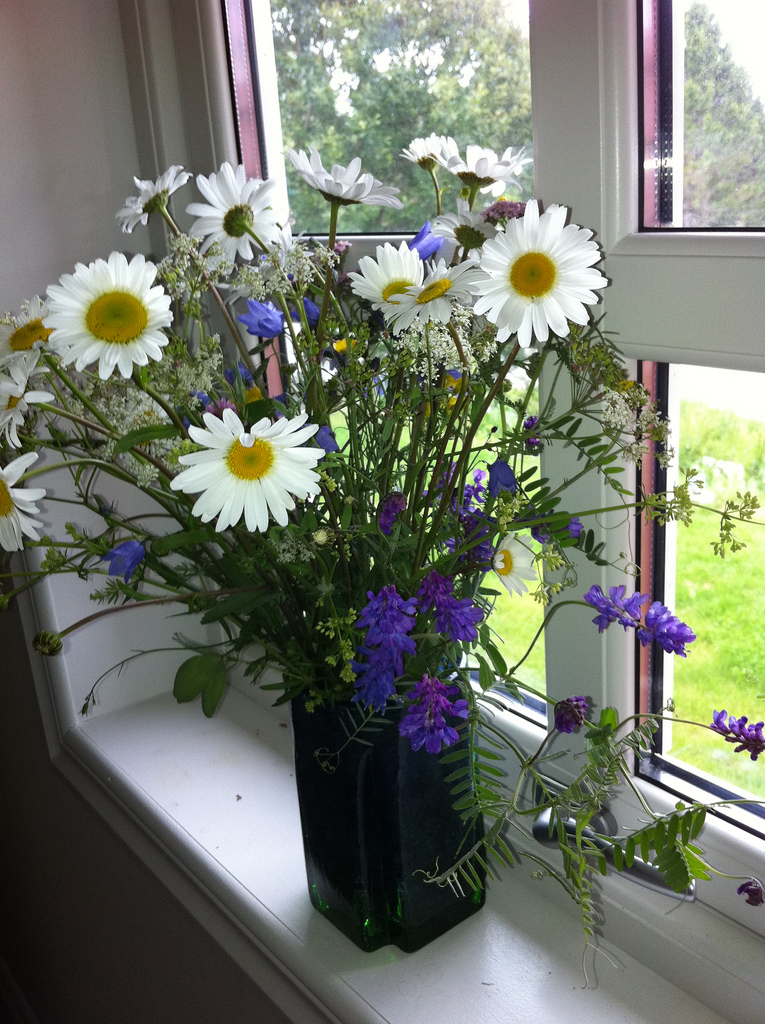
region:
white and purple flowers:
[100, 168, 655, 738]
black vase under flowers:
[240, 647, 515, 994]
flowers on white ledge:
[76, 433, 572, 1003]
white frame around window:
[222, 20, 746, 887]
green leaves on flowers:
[76, 103, 720, 811]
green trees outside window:
[268, 0, 488, 227]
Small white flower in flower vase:
[172, 408, 330, 535]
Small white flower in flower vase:
[463, 191, 611, 353]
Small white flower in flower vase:
[42, 240, 170, 384]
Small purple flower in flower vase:
[391, 663, 481, 758]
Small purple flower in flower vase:
[338, 578, 427, 715]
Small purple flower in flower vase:
[420, 559, 488, 654]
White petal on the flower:
[520, 187, 537, 248]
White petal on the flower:
[201, 412, 235, 446]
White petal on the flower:
[257, 474, 297, 530]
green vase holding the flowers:
[259, 638, 503, 958]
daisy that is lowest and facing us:
[167, 402, 332, 554]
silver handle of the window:
[532, 762, 710, 929]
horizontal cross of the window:
[236, 212, 760, 379]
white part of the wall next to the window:
[0, 13, 175, 253]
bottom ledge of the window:
[88, 682, 714, 1021]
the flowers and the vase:
[1, 128, 763, 948]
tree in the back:
[273, 2, 525, 243]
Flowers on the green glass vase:
[1, 128, 761, 956]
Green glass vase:
[281, 683, 490, 955]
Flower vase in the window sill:
[0, 2, 759, 1021]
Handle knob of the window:
[524, 769, 697, 902]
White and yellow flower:
[168, 404, 327, 535]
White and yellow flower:
[39, 247, 175, 381]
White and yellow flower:
[467, 197, 611, 352]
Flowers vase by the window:
[2, 3, 763, 1019]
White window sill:
[32, 671, 760, 1019]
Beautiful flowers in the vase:
[1, 128, 760, 955]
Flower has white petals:
[39, 248, 174, 381]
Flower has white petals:
[467, 196, 611, 353]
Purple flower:
[95, 539, 147, 580]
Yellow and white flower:
[165, 405, 328, 535]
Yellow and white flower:
[467, 197, 610, 349]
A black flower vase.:
[292, 651, 489, 937]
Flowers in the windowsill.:
[4, 81, 762, 1005]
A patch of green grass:
[316, 358, 761, 806]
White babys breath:
[73, 229, 734, 588]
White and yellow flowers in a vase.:
[5, 114, 607, 644]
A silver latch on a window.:
[532, 773, 682, 897]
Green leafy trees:
[264, 3, 761, 359]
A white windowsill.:
[55, 620, 692, 1021]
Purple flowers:
[322, 402, 761, 810]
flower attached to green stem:
[40, 249, 171, 376]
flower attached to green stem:
[0, 360, 59, 447]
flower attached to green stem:
[0, 447, 55, 558]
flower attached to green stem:
[165, 400, 322, 530]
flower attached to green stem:
[120, 165, 192, 228]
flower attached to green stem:
[188, 164, 278, 260]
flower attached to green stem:
[289, 142, 403, 221]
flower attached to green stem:
[355, 236, 423, 314]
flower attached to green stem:
[491, 527, 541, 592]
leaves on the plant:
[559, 837, 590, 901]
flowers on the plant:
[342, 602, 464, 746]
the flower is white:
[232, 488, 317, 520]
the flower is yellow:
[501, 247, 556, 298]